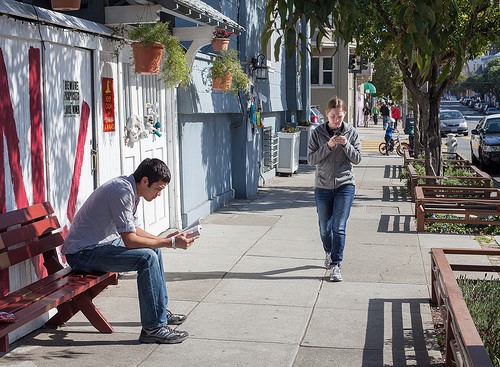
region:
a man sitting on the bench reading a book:
[91, 169, 216, 344]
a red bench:
[5, 209, 59, 334]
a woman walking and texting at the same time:
[316, 105, 356, 280]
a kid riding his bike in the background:
[378, 120, 404, 150]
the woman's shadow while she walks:
[187, 265, 304, 283]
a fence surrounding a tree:
[425, 245, 469, 365]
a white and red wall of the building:
[14, 107, 81, 179]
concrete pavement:
[230, 285, 355, 345]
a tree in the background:
[400, 55, 451, 180]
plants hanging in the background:
[153, 57, 244, 83]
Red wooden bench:
[0, 199, 117, 364]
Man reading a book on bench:
[59, 144, 201, 359]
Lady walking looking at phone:
[307, 82, 361, 284]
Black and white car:
[466, 116, 499, 173]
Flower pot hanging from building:
[119, 7, 188, 89]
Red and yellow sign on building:
[87, 66, 127, 141]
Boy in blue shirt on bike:
[365, 113, 415, 160]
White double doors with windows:
[117, 46, 194, 267]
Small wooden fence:
[426, 243, 496, 364]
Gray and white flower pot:
[274, 116, 303, 186]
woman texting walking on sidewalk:
[309, 94, 360, 283]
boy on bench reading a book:
[63, 157, 203, 342]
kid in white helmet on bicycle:
[378, 117, 409, 156]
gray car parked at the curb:
[436, 106, 467, 135]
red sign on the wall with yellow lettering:
[101, 76, 116, 132]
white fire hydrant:
[443, 131, 458, 157]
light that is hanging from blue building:
[253, 54, 269, 81]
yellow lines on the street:
[356, 137, 447, 152]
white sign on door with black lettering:
[61, 78, 79, 115]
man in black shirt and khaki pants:
[363, 103, 371, 128]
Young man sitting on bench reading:
[57, 155, 202, 345]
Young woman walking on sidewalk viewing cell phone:
[301, 92, 361, 278]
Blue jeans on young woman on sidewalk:
[310, 180, 350, 267]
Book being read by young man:
[175, 216, 201, 241]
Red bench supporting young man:
[1, 200, 117, 355]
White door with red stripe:
[42, 45, 98, 265]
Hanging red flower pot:
[130, 40, 162, 75]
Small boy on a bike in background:
[382, 116, 397, 152]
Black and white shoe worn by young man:
[137, 325, 187, 342]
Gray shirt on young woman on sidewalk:
[304, 122, 361, 189]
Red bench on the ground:
[0, 202, 62, 353]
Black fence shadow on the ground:
[363, 285, 442, 365]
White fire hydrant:
[443, 130, 458, 157]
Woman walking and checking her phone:
[313, 92, 360, 282]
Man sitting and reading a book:
[68, 152, 201, 341]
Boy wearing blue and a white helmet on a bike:
[378, 115, 412, 155]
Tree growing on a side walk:
[380, 0, 469, 187]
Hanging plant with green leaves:
[112, 0, 191, 85]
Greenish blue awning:
[351, 77, 380, 97]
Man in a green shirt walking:
[369, 102, 380, 125]